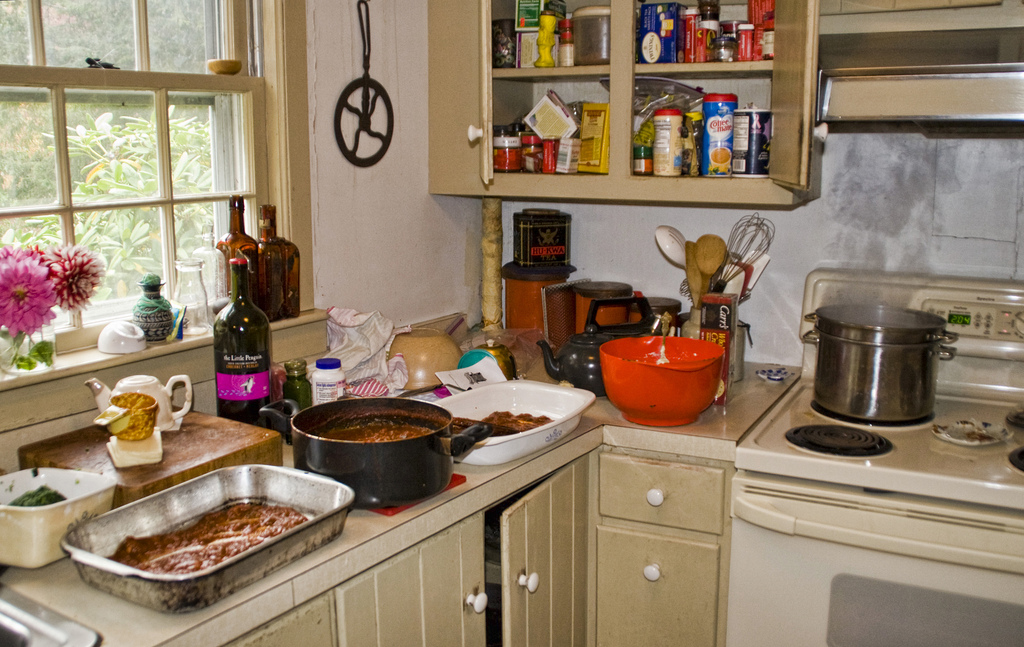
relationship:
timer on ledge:
[81, 318, 155, 354] [5, 309, 347, 465]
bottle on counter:
[200, 257, 276, 429] [0, 361, 791, 643]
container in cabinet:
[725, 104, 771, 188] [420, 9, 818, 211]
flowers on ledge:
[4, 252, 96, 363] [1, 301, 337, 470]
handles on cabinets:
[639, 485, 663, 590] [554, 388, 769, 644]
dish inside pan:
[60, 463, 356, 614] [58, 457, 349, 607]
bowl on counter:
[600, 336, 726, 427] [0, 361, 791, 643]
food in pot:
[297, 415, 435, 442] [285, 399, 448, 499]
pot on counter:
[288, 393, 462, 511] [0, 361, 791, 643]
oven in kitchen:
[728, 267, 1024, 646] [9, 4, 1018, 616]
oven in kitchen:
[728, 263, 1022, 644] [9, 4, 1018, 616]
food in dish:
[104, 503, 307, 576] [57, 459, 358, 612]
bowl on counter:
[597, 332, 730, 432] [0, 361, 791, 643]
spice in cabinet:
[518, 133, 544, 173] [426, 0, 822, 228]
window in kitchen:
[0, 0, 236, 100] [9, 4, 1018, 616]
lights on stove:
[994, 306, 1014, 349] [708, 215, 1022, 647]